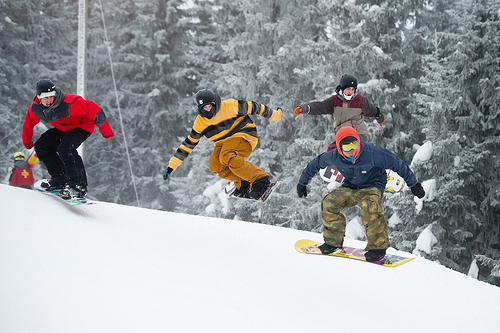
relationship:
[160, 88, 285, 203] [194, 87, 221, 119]
person wearing hat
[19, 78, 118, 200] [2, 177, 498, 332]
person on slope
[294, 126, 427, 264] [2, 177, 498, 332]
man on slope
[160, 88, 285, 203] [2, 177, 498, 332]
person on slope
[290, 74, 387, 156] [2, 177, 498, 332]
person on slope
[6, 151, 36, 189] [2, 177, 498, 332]
person behind slope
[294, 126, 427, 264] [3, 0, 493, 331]
man at a ski resort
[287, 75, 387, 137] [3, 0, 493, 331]
person at a ski resort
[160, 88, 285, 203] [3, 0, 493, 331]
person at a ski resort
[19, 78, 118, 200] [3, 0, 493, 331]
person at a ski resort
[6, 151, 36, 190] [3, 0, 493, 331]
person at a ski resort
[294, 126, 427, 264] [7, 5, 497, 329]
man enjoy day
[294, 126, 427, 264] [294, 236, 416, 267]
man standing on board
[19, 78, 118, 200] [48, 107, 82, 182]
person wearing clothing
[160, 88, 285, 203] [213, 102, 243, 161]
person wearing clothing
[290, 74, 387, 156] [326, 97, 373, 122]
person wearing clothing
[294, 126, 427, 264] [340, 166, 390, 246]
man wearing clothing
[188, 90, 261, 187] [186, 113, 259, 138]
person wearing shirt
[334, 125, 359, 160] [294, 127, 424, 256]
hat in man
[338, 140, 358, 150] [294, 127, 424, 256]
goggles in man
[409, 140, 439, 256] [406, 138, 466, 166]
snow on branch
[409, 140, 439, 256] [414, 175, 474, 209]
snow on branch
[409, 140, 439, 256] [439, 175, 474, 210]
snow on branch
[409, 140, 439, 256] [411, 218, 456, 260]
snow on branch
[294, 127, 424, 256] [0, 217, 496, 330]
man crouched over slope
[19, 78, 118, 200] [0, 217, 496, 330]
person crouched over slope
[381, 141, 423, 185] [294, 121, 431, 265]
arm on snowboarder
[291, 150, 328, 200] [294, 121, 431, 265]
arm on snowboarder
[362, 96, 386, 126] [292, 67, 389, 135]
arm on snowboarder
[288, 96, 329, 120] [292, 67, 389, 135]
arm on snowboarder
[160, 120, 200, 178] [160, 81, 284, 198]
arm on snowboarder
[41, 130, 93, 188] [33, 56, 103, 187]
pants on man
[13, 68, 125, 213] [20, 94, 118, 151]
person wearing red and gray clothing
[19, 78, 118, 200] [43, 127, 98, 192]
person wearing black pants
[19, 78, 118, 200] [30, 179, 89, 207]
person on board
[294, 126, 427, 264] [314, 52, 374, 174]
man are wearing hats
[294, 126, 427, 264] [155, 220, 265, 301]
man are playing in snow